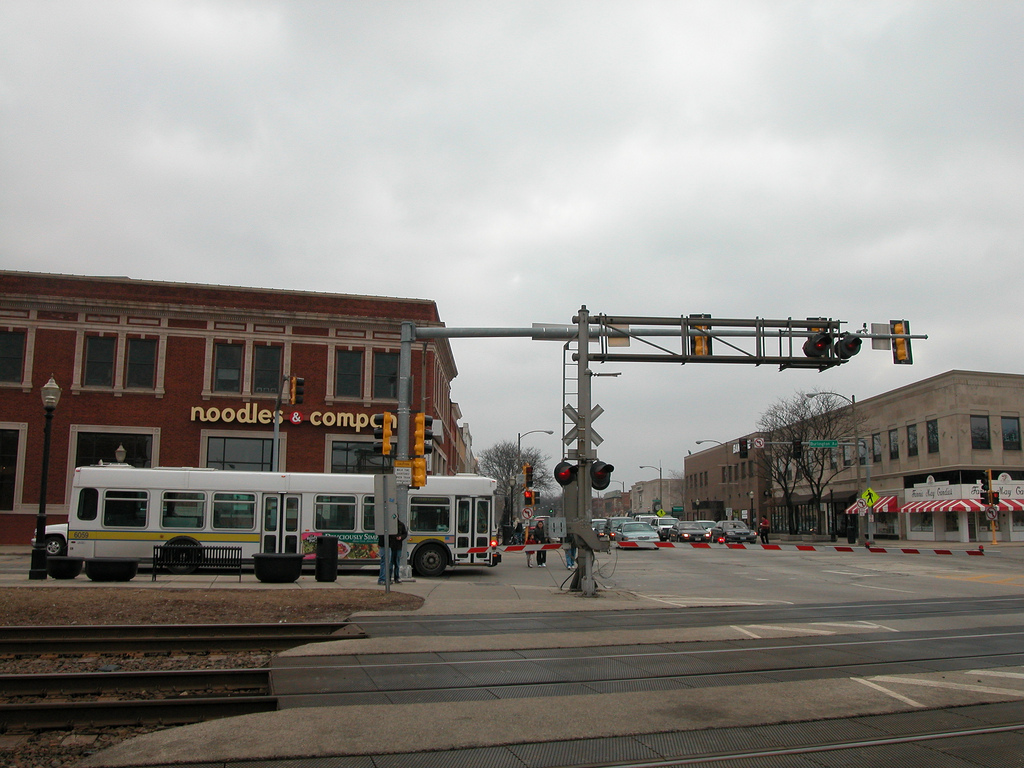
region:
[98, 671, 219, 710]
train tracks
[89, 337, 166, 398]
two windows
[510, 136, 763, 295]
clouds in the sky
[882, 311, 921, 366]
a traffic light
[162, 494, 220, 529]
window on the bus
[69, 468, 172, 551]
the bus is white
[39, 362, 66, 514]
a street light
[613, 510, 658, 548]
a car on the street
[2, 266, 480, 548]
the tall brick building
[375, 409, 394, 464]
the hanging yellow traffic light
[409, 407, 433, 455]
the hanging yellow traffic light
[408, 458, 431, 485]
the hanging yellow traffic light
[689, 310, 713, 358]
the hanging yellow traffic light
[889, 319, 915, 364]
the hanging yellow traffic light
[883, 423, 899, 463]
the window of the building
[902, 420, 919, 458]
the window of the building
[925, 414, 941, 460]
the window of the building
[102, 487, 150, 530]
the large window of the bus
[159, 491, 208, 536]
the large window of the bus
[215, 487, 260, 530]
the large window of the bus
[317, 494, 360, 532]
the large window of the bus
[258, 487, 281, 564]
the door of the bus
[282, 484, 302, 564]
the door of the bus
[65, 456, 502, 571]
the long white bus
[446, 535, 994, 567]
the red and white long track gate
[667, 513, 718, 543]
the parked car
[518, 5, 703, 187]
grey and white sky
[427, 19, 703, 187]
white clouds in sky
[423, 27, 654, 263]
thick clouds in sky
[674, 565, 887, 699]
road is light grey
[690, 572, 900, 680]
white lines on road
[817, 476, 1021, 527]
red and white awning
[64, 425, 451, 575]
white and yellow bus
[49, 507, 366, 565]
yellow stripe on bus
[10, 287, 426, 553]
building is red brick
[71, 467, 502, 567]
A long bus at a traffic light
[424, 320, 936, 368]
A long pole with traffic lights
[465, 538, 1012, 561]
A red and white barrier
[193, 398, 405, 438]
A sign on a wall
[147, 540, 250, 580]
A black bench on a sidewalk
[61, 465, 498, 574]
a long white bus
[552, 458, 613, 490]
electronic train warning signal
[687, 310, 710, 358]
back of electric traffic signal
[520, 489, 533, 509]
an electric traffic signal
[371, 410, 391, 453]
an electric traffic signal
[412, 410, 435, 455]
an electric traffic signal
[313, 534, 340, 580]
a large public trash can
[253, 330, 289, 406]
A window on a building.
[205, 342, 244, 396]
A window on a building.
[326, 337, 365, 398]
A window on a building.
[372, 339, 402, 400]
A window on a building.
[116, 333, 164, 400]
A window on a building.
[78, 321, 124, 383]
A window on a building.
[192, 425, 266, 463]
A window on a building.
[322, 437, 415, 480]
A window on a building.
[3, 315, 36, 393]
A window on a building.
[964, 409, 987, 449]
A window on a building.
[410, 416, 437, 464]
Traffic light on the pole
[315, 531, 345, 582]
Trash can on the streetn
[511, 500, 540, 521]
do not turn sign on the pole